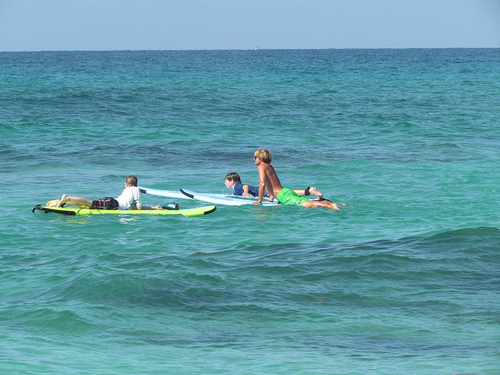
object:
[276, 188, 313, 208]
trunks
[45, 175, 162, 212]
boy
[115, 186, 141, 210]
white shirt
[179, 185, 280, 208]
surfboard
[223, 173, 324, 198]
boy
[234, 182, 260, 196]
blue shirt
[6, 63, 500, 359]
water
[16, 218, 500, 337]
wave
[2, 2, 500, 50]
sky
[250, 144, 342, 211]
blond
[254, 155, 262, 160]
sunglasses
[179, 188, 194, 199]
black tip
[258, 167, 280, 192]
torso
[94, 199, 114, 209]
plaid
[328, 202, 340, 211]
bare feet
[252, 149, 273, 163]
hair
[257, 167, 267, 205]
arm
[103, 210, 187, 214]
green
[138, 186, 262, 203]
surf board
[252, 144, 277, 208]
up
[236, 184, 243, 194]
blue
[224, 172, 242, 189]
head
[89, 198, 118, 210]
shorts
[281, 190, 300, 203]
green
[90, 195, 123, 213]
trunks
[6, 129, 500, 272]
waves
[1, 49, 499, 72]
darker blue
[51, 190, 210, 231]
surfboard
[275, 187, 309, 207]
shorts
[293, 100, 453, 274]
ocean